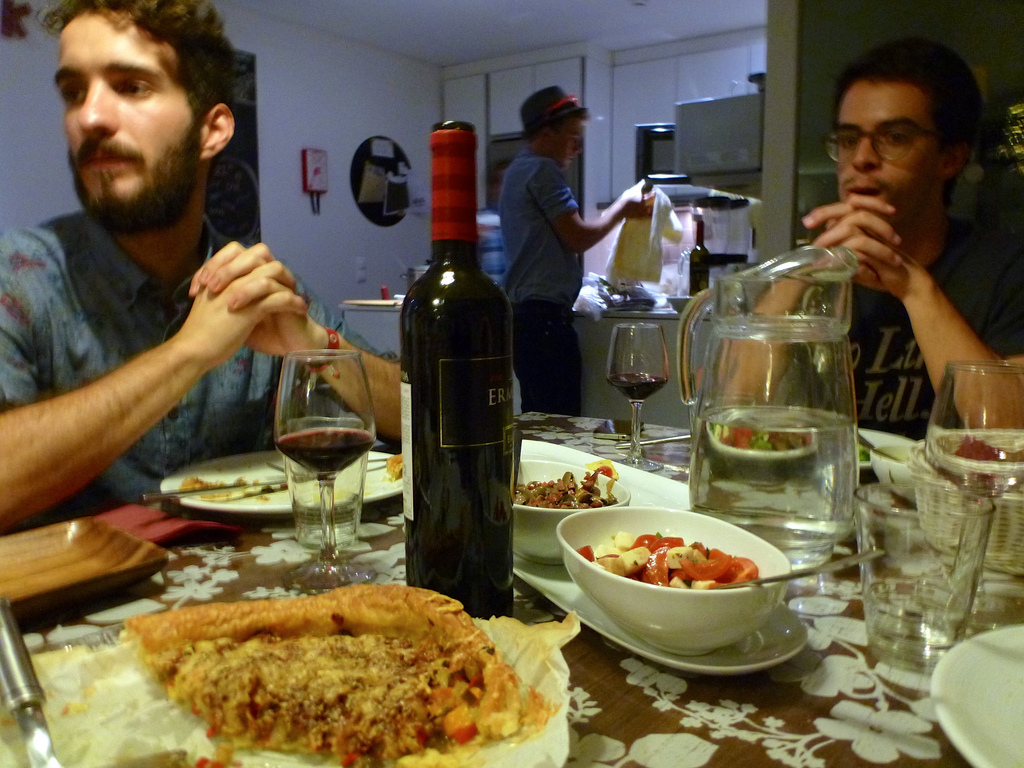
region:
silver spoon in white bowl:
[717, 518, 911, 602]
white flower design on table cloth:
[621, 666, 846, 755]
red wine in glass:
[264, 414, 385, 479]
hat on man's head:
[492, 56, 614, 136]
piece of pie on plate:
[150, 562, 550, 739]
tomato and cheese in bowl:
[605, 482, 748, 588]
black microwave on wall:
[625, 103, 712, 171]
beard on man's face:
[14, 157, 240, 240]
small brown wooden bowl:
[30, 496, 161, 579]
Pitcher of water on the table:
[661, 224, 868, 592]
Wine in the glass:
[267, 334, 388, 592]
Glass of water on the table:
[846, 470, 995, 677]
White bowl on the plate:
[557, 492, 801, 651]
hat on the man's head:
[513, 76, 599, 190]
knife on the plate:
[134, 452, 299, 511]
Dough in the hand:
[588, 154, 699, 292]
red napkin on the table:
[96, 496, 243, 550]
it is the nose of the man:
[75, 94, 120, 143]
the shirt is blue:
[9, 209, 291, 454]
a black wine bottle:
[366, 101, 538, 585]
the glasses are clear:
[817, 114, 928, 173]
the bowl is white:
[558, 503, 794, 644]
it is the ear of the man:
[189, 95, 246, 160]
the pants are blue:
[518, 297, 588, 409]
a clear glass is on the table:
[841, 474, 982, 700]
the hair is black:
[852, 34, 958, 123]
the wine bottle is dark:
[400, 121, 512, 618]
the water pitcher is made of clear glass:
[677, 240, 858, 588]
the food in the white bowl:
[557, 505, 792, 657]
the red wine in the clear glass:
[275, 351, 377, 590]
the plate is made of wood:
[1, 515, 173, 626]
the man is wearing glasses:
[724, 37, 1022, 436]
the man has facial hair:
[0, 0, 400, 535]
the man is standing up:
[501, 82, 663, 416]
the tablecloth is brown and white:
[2, 407, 1018, 766]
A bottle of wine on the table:
[411, 289, 504, 584]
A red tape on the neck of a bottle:
[432, 134, 474, 233]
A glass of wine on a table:
[287, 355, 357, 431]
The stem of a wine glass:
[322, 479, 333, 553]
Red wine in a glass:
[286, 436, 363, 449]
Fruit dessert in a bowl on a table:
[622, 537, 703, 576]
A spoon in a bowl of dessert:
[812, 564, 838, 569]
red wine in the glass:
[264, 340, 383, 598]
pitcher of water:
[665, 225, 874, 576]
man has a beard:
[66, 102, 215, 238]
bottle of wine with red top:
[352, 81, 548, 635]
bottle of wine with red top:
[349, 95, 549, 623]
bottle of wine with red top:
[354, 88, 550, 629]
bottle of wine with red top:
[355, 104, 551, 617]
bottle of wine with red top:
[365, 91, 555, 624]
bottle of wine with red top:
[358, 101, 559, 634]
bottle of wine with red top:
[355, 83, 558, 628]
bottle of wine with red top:
[351, 105, 548, 637]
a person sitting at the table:
[845, 13, 1011, 214]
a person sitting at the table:
[58, 51, 420, 507]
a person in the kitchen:
[453, 31, 651, 376]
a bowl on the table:
[564, 487, 681, 665]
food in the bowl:
[634, 531, 677, 574]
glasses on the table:
[781, 437, 1020, 641]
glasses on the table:
[886, 338, 1008, 490]